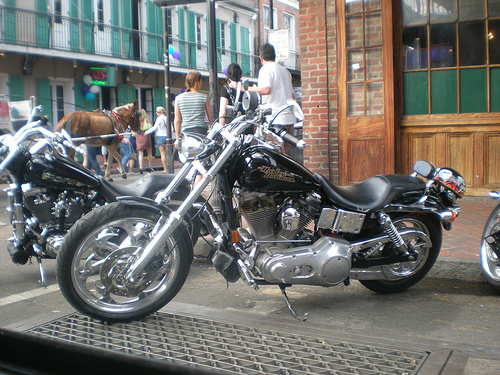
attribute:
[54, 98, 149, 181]
horse — brown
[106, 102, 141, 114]
mane — white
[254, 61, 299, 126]
shirt — white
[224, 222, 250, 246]
reflector — orange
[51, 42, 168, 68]
floor — upper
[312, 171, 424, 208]
seat — black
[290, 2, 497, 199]
building — brick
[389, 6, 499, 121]
window — wood, wooden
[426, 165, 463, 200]
helmet — black and silver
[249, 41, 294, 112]
man — white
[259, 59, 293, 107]
shirt — short sleeved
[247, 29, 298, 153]
man — black haired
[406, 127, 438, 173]
panel — wooden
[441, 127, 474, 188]
panel — wooden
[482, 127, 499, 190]
panel — wooden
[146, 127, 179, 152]
shorts — blue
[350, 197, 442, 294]
wheel — rear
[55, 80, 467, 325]
harley davidson — black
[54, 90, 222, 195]
pony — brown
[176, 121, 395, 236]
motorcycles — black, chrome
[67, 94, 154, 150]
horse — brown, white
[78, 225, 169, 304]
rim — chrome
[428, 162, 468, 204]
helmet — black and orange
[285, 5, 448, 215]
building — brick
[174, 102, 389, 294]
detailing — chrome